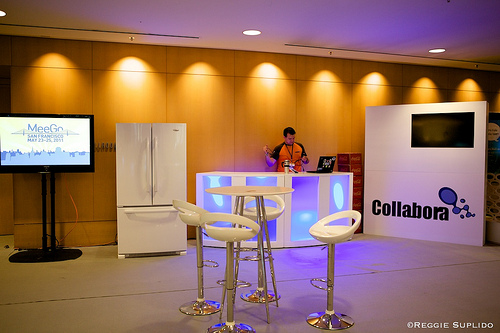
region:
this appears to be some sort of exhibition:
[0, 13, 492, 325]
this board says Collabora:
[368, 93, 492, 253]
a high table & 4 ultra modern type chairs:
[158, 180, 374, 327]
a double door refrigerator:
[111, 113, 199, 255]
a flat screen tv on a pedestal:
[1, 110, 103, 260]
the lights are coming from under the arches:
[33, 50, 476, 110]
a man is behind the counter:
[252, 123, 311, 185]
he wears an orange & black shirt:
[266, 123, 318, 172]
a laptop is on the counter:
[296, 146, 344, 176]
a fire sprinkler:
[119, 32, 141, 49]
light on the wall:
[257, 57, 293, 88]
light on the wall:
[168, 45, 215, 103]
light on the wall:
[95, 42, 169, 83]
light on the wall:
[45, 55, 74, 85]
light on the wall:
[306, 75, 346, 100]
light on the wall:
[356, 66, 393, 98]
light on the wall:
[441, 72, 491, 105]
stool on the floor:
[313, 191, 369, 323]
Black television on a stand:
[0, 105, 95, 261]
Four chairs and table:
[165, 180, 365, 330]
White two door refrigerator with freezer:
[110, 115, 190, 265]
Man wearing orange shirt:
[260, 125, 305, 175]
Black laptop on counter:
[190, 150, 355, 250]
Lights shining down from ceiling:
[0, 0, 495, 115]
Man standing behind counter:
[190, 120, 350, 250]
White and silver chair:
[300, 205, 360, 330]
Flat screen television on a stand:
[0, 105, 95, 260]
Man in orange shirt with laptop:
[255, 121, 340, 176]